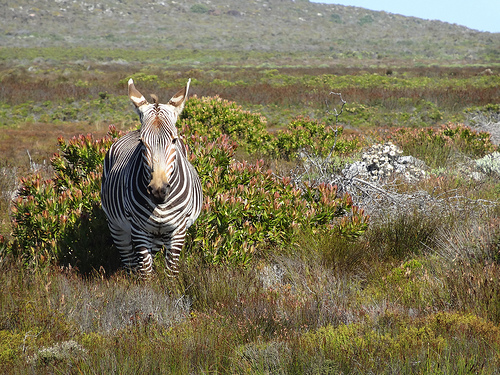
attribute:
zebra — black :
[97, 71, 207, 280]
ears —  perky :
[120, 65, 192, 108]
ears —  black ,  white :
[125, 69, 196, 119]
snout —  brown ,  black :
[147, 180, 168, 202]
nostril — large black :
[141, 174, 171, 206]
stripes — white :
[112, 150, 162, 224]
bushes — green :
[204, 93, 359, 252]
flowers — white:
[220, 136, 354, 250]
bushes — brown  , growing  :
[224, 134, 284, 206]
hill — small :
[8, 1, 478, 72]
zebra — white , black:
[92, 71, 210, 296]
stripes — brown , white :
[167, 197, 192, 230]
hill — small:
[7, 9, 464, 69]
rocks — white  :
[326, 140, 427, 207]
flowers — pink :
[221, 144, 280, 224]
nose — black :
[146, 173, 169, 204]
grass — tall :
[244, 223, 405, 353]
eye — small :
[140, 135, 177, 149]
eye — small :
[139, 129, 179, 150]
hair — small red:
[150, 109, 165, 122]